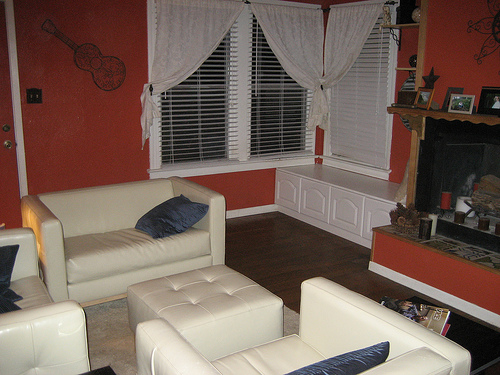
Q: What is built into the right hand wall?
A: A fireplace.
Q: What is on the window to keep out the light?
A: Blinds?.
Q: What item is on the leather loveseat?
A: A blue pillow.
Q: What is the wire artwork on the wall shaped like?
A: A guitar.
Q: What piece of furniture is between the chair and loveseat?
A: And ottoman.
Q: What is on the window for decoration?
A: Curtains.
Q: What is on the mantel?
A: Framed photographs.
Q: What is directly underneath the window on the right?
A: A window seat.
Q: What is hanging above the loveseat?
A: A guitar decoration.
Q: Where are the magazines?
A: On a table.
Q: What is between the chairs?
A: An ottoman.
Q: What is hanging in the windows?
A: White curtains.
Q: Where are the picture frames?
A: On the mantle.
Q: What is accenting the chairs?
A: Blue pillows.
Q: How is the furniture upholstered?
A: With white leather.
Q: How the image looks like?
A: Great.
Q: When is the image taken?
A: When room is empty.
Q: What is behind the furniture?
A: Windows.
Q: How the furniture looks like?
A: Good.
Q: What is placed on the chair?
A: Pillow.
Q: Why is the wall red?
A: Elegant.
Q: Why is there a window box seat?
A: To secure.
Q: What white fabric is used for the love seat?
A: Leather.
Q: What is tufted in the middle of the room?
A: White ottoman.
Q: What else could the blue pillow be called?
A: Accent piece.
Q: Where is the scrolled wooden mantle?
A: Over fireplace.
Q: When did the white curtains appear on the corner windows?
A: Redecorating.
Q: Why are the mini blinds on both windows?
A: Privacy.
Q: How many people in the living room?
A: Zero.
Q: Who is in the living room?
A: No one.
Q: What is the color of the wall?
A: Orange.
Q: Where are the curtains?
A: On the window.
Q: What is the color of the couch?
A: White.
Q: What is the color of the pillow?
A: Blue.